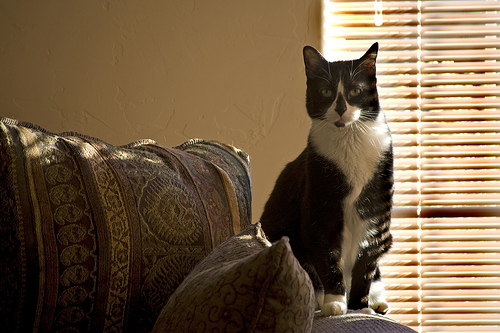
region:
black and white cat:
[258, 33, 419, 319]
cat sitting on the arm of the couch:
[265, 33, 415, 330]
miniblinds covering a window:
[390, 3, 499, 324]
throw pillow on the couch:
[135, 204, 312, 331]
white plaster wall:
[15, 5, 275, 137]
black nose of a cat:
[329, 100, 351, 119]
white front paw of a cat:
[320, 288, 350, 316]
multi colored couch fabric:
[5, 121, 254, 301]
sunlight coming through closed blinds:
[358, 3, 495, 313]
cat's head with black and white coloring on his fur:
[300, 43, 386, 136]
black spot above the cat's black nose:
[336, 94, 346, 115]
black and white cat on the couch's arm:
[258, 43, 389, 315]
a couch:
[4, 120, 419, 331]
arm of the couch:
[309, 308, 416, 332]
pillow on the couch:
[152, 223, 314, 331]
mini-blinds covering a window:
[327, 2, 497, 331]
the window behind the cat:
[325, 2, 495, 332]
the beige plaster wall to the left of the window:
[2, 1, 322, 221]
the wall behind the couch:
[1, 0, 322, 225]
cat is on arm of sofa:
[282, 37, 424, 293]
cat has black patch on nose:
[327, 88, 347, 123]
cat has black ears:
[302, 48, 379, 82]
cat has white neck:
[285, 117, 400, 197]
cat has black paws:
[335, 254, 385, 317]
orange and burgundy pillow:
[8, 140, 230, 272]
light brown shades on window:
[362, 25, 492, 225]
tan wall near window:
[9, 0, 231, 82]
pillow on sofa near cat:
[172, 219, 316, 327]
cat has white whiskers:
[308, 94, 393, 136]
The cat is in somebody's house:
[20, 25, 490, 325]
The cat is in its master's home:
[22, 35, 475, 320]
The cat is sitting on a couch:
[36, 15, 484, 315]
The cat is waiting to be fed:
[36, 17, 496, 308]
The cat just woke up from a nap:
[35, 25, 492, 318]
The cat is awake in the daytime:
[37, 30, 472, 325]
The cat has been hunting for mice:
[47, 35, 484, 322]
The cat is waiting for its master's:
[40, 32, 485, 320]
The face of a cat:
[310, 61, 366, 121]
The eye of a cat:
[318, 85, 335, 100]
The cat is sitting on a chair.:
[0, 43, 394, 331]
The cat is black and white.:
[262, 43, 394, 226]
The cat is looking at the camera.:
[263, 41, 392, 224]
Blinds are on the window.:
[418, 0, 498, 330]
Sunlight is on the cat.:
[356, 207, 388, 249]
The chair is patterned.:
[7, 155, 229, 265]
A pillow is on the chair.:
[151, 223, 311, 332]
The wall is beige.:
[0, 0, 277, 105]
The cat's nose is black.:
[332, 90, 348, 115]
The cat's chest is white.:
[335, 129, 381, 164]